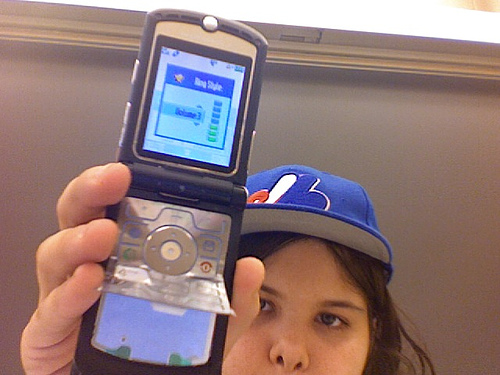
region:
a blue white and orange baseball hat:
[240, 164, 395, 266]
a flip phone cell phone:
[75, 2, 247, 373]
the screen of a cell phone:
[140, 39, 235, 168]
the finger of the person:
[17, 265, 108, 370]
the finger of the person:
[32, 221, 112, 284]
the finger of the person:
[55, 162, 124, 217]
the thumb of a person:
[224, 255, 262, 359]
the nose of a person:
[272, 328, 312, 368]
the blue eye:
[257, 296, 277, 315]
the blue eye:
[315, 311, 346, 326]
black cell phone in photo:
[108, 12, 263, 365]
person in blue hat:
[239, 152, 418, 320]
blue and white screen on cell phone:
[144, 17, 240, 188]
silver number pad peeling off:
[114, 192, 240, 332]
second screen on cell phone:
[98, 225, 222, 364]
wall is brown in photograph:
[20, 22, 435, 242]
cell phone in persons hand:
[46, 125, 261, 374]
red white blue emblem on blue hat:
[243, 152, 336, 216]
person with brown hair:
[258, 194, 438, 374]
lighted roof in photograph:
[279, 0, 452, 72]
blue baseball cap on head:
[234, 150, 403, 265]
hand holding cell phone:
[43, 12, 278, 357]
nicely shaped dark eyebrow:
[309, 286, 379, 318]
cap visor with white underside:
[218, 202, 405, 260]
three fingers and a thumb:
[18, 147, 283, 357]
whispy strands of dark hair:
[363, 273, 465, 373]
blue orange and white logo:
[238, 165, 357, 228]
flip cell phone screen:
[110, 8, 286, 193]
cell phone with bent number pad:
[84, 6, 234, 374]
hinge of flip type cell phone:
[91, 145, 264, 212]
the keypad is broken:
[67, 202, 251, 347]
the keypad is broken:
[116, 241, 206, 363]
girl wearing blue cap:
[359, 205, 365, 212]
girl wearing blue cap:
[359, 210, 365, 226]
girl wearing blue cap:
[351, 210, 357, 240]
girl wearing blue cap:
[352, 211, 364, 246]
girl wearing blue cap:
[362, 221, 367, 246]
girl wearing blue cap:
[339, 207, 348, 235]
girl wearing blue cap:
[358, 212, 365, 247]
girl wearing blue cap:
[347, 208, 359, 235]